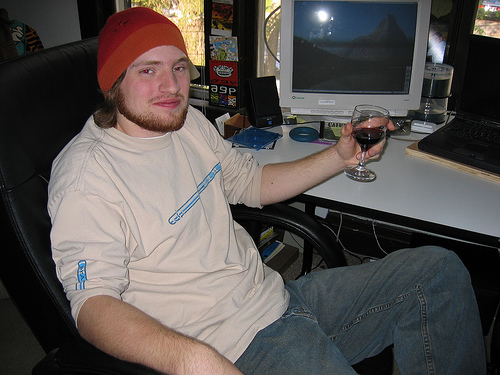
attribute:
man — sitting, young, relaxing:
[48, 7, 490, 375]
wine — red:
[352, 128, 385, 145]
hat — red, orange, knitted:
[95, 5, 189, 100]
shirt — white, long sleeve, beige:
[46, 104, 291, 363]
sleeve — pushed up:
[199, 109, 265, 212]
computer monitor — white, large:
[279, 2, 430, 125]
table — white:
[226, 109, 500, 282]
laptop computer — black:
[417, 33, 499, 177]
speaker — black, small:
[237, 75, 283, 130]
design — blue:
[164, 161, 224, 224]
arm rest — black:
[231, 203, 348, 267]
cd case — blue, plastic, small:
[227, 125, 283, 149]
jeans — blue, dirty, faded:
[232, 244, 487, 375]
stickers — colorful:
[208, 1, 240, 109]